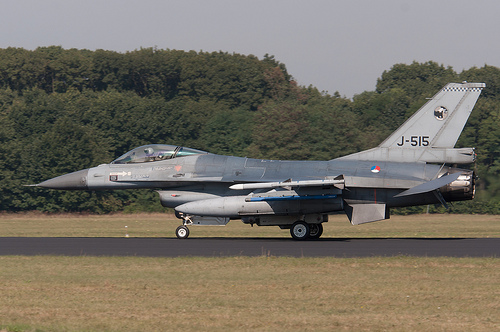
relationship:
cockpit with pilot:
[110, 144, 207, 165] [139, 145, 158, 162]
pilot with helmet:
[143, 147, 158, 166] [144, 147, 155, 155]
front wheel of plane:
[174, 223, 189, 239] [18, 71, 498, 243]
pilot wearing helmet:
[143, 147, 158, 166] [141, 146, 155, 156]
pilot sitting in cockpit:
[143, 147, 158, 166] [88, 140, 198, 187]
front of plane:
[17, 177, 36, 190] [42, 111, 490, 234]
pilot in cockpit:
[143, 147, 158, 166] [105, 143, 218, 173]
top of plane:
[106, 140, 213, 167] [18, 71, 498, 243]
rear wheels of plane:
[287, 221, 324, 238] [21, 77, 491, 235]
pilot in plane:
[140, 136, 164, 180] [42, 82, 444, 250]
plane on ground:
[18, 71, 498, 243] [2, 207, 496, 330]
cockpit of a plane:
[110, 144, 207, 165] [18, 71, 498, 243]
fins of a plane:
[390, 172, 476, 200] [51, 128, 453, 231]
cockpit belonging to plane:
[109, 140, 210, 166] [18, 71, 498, 243]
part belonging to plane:
[108, 141, 209, 166] [21, 77, 491, 235]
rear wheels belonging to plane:
[290, 221, 311, 240] [21, 77, 491, 235]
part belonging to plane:
[378, 80, 485, 146] [21, 77, 491, 235]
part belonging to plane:
[433, 167, 476, 198] [21, 77, 491, 235]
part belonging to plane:
[231, 174, 345, 192] [21, 77, 491, 235]